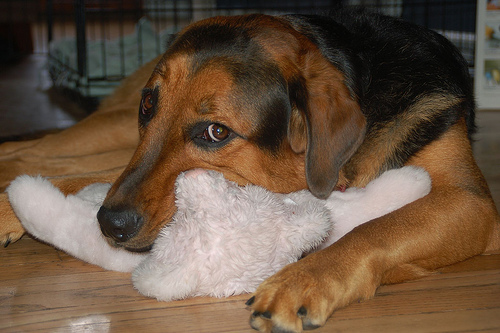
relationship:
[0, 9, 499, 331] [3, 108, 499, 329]
dog on floor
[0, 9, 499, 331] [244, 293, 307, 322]
dog has claws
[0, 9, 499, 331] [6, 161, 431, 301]
dog resting on teddy bear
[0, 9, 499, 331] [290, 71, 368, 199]
dog has ear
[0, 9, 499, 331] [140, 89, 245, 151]
dog has eyes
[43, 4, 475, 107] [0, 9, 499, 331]
cage behind dog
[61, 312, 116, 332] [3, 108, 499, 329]
reflection on floor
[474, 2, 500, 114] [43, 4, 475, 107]
picture next to cage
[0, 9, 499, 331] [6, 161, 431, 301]
dog laying on teddy bear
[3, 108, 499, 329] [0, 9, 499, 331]
floor under dog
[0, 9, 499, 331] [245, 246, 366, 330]
dog has paw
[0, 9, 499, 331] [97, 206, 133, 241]
dog has nose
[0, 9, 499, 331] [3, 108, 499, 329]
dog lying on floor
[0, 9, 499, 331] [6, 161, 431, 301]
dog cuddling teddy bear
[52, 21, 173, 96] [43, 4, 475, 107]
cloth in cage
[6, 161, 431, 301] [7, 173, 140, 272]
teddy bear has arm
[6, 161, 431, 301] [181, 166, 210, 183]
teddy bear has nose